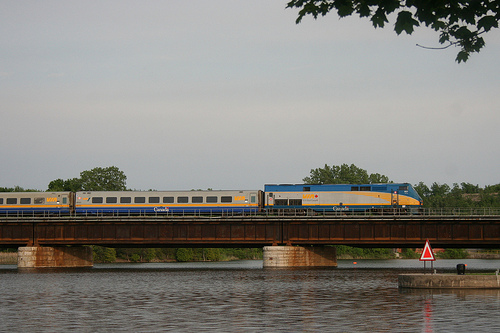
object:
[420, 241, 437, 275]
sign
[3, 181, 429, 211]
train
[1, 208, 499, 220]
fencing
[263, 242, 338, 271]
pillar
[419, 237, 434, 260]
warning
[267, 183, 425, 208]
lead car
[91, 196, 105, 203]
windows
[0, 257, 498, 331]
water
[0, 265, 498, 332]
ripples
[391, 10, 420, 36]
leaves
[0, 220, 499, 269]
bridge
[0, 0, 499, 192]
sky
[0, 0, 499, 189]
dark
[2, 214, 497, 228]
tracks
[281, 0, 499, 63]
tree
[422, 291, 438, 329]
reflection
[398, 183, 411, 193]
window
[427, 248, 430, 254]
red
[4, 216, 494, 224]
edge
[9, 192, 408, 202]
side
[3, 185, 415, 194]
edge